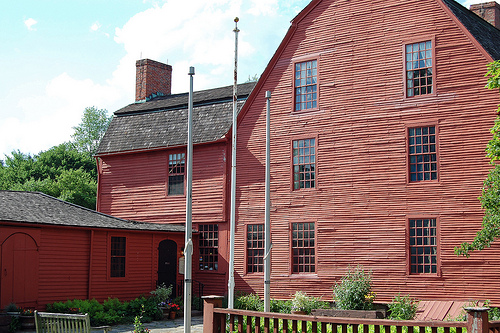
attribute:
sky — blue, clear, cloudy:
[0, 3, 499, 165]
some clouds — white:
[7, 11, 139, 159]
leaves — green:
[2, 104, 115, 213]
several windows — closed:
[291, 35, 447, 284]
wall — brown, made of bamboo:
[97, 2, 499, 299]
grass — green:
[228, 298, 499, 333]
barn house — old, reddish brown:
[2, 1, 499, 322]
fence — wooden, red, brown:
[198, 287, 498, 332]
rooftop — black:
[100, 75, 259, 146]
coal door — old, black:
[157, 236, 177, 297]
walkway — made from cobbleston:
[93, 314, 205, 333]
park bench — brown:
[31, 305, 108, 332]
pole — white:
[182, 66, 201, 332]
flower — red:
[168, 299, 180, 311]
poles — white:
[180, 10, 273, 332]